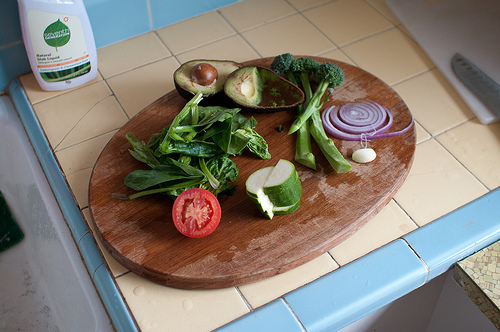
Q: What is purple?
A: Onion.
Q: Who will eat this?
A: Men.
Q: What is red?
A: Tomato.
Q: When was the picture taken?
A: Daytime.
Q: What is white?
A: Counter top.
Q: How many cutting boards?
A: One.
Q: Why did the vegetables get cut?
A: To prepare to eat.